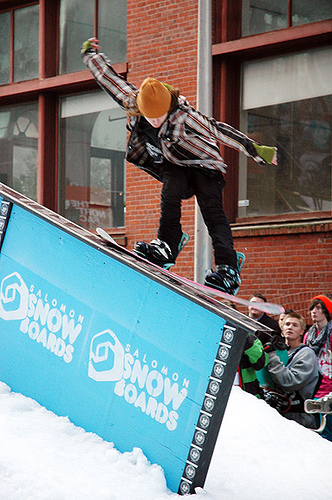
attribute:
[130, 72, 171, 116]
beanie — orange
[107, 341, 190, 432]
lettering — white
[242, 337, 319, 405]
sweater — gray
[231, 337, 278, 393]
stripes — green, Black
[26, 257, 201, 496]
sign — blue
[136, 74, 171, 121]
hat — orange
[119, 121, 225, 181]
jacket — striped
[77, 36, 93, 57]
gloves — green, fingerless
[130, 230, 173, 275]
shoe — teal, black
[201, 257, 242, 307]
shoe — teal, black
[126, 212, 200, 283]
boot — black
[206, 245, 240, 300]
boot — black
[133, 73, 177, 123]
hat — brown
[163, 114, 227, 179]
shirt — striped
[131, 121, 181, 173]
shirt — black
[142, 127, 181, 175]
shirt — black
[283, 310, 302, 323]
hair — blonde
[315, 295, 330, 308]
hat — red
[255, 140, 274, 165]
glove — green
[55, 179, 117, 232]
sign — red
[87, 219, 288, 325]
snowboard — black, red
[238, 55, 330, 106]
blind — white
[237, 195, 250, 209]
sticker — white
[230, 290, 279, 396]
person — black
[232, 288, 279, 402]
shirt — green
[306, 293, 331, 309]
head warmer — orange